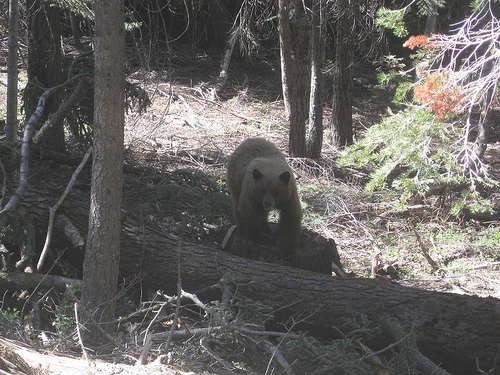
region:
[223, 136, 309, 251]
Brown bear walking in woods.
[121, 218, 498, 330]
Fallen tree trunk in woods.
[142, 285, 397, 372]
Various sticks fallen around forest.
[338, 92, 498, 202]
Green leaves on tree branch.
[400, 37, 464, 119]
Reddish leaves on tree branch.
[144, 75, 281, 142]
Sunlight breaking through trees.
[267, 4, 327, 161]
Pine tree trunks in forest.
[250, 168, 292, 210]
Head of a brown bear.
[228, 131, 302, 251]
Bear on all fours.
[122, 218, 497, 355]
Pine tree trunk fallen in forest.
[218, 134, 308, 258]
large bear crawling throughwoods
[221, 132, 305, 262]
bear is very large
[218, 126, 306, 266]
bear is light brown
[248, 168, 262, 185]
bears right ear is black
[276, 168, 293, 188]
bears left ear is black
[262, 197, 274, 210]
bears nose is black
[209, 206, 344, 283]
bear is standing on tree stump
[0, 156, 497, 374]
large tree is down on ground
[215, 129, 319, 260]
large bear is stepping on stump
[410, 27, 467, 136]
parts of leaves of tree are dead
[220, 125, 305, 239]
bear on the ground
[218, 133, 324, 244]
bear on all fours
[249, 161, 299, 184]
pair of ears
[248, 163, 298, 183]
two small ears on the top of the head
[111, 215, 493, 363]
log laying on the ground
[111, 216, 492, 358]
bark on the log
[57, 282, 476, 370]
sticks on the ground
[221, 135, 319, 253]
brown fur on the bear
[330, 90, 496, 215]
green leaves on the branches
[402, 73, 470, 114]
orange leaves on the branches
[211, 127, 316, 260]
bear is color brown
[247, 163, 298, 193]
pointy ears of bear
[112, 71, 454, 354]
a bear in the forest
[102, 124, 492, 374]
a log close a bear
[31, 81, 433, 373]
dead branches on ground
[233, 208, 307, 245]
front legs of bear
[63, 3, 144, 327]
trunk is color brown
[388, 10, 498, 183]
branches with red flowers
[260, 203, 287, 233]
snout of bear is long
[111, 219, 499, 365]
a log in the forest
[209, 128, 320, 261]
bear in forest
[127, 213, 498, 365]
fallen tree log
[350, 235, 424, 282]
sticks and dirt on ground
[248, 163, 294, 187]
two bear ears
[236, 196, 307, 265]
two bear front legs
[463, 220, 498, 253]
grass in ground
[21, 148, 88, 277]
tree branch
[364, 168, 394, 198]
pine needles on tree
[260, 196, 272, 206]
nose on bear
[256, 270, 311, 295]
striation marks on tree log